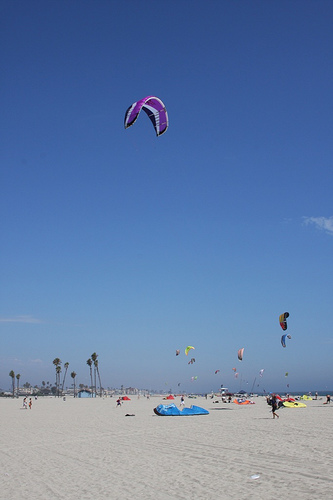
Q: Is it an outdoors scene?
A: Yes, it is outdoors.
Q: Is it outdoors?
A: Yes, it is outdoors.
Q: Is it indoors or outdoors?
A: It is outdoors.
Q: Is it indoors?
A: No, it is outdoors.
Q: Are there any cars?
A: No, there are no cars.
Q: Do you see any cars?
A: No, there are no cars.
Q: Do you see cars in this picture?
A: No, there are no cars.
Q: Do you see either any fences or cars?
A: No, there are no cars or fences.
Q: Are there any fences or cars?
A: No, there are no cars or fences.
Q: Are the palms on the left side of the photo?
A: Yes, the palms are on the left of the image.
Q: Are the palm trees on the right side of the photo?
A: No, the palm trees are on the left of the image.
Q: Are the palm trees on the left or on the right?
A: The palm trees are on the left of the image.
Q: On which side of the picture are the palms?
A: The palms are on the left of the image.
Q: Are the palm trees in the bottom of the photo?
A: Yes, the palm trees are in the bottom of the image.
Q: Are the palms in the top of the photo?
A: No, the palms are in the bottom of the image.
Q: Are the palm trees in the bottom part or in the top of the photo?
A: The palm trees are in the bottom of the image.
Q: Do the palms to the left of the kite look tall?
A: Yes, the palms are tall.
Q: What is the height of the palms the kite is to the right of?
A: The palm trees are tall.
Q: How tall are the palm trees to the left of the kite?
A: The palms are tall.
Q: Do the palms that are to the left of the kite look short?
A: No, the palms are tall.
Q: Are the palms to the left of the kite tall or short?
A: The palm trees are tall.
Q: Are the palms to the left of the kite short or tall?
A: The palm trees are tall.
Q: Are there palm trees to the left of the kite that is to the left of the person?
A: Yes, there are palm trees to the left of the kite.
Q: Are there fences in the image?
A: No, there are no fences.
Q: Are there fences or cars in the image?
A: No, there are no fences or cars.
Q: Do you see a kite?
A: Yes, there is a kite.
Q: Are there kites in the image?
A: Yes, there is a kite.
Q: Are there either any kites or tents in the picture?
A: Yes, there is a kite.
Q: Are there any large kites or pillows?
A: Yes, there is a large kite.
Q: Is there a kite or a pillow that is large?
A: Yes, the kite is large.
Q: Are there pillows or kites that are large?
A: Yes, the kite is large.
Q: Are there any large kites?
A: Yes, there is a large kite.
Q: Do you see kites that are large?
A: Yes, there is a kite that is large.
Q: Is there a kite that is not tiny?
A: Yes, there is a large kite.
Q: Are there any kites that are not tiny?
A: Yes, there is a large kite.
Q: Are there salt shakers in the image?
A: No, there are no salt shakers.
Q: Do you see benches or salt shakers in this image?
A: No, there are no salt shakers or benches.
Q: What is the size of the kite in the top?
A: The kite is large.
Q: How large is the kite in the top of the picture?
A: The kite is large.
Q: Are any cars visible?
A: No, there are no cars.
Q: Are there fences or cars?
A: No, there are no cars or fences.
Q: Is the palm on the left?
A: Yes, the palm is on the left of the image.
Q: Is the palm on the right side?
A: No, the palm is on the left of the image.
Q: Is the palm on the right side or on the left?
A: The palm is on the left of the image.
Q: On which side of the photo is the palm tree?
A: The palm tree is on the left of the image.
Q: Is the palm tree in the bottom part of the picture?
A: Yes, the palm tree is in the bottom of the image.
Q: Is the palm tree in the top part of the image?
A: No, the palm tree is in the bottom of the image.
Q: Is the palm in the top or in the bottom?
A: The palm is in the bottom of the image.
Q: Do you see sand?
A: Yes, there is sand.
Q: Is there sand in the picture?
A: Yes, there is sand.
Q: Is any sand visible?
A: Yes, there is sand.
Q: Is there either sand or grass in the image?
A: Yes, there is sand.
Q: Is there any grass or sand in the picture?
A: Yes, there is sand.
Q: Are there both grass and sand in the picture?
A: No, there is sand but no grass.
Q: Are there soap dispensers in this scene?
A: No, there are no soap dispensers.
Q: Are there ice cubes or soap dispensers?
A: No, there are no soap dispensers or ice cubes.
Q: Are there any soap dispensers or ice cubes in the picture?
A: No, there are no soap dispensers or ice cubes.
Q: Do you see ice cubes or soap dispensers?
A: No, there are no soap dispensers or ice cubes.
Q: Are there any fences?
A: No, there are no fences.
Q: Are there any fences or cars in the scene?
A: No, there are no fences or cars.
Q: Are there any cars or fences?
A: No, there are no fences or cars.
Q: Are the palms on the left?
A: Yes, the palms are on the left of the image.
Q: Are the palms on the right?
A: No, the palms are on the left of the image.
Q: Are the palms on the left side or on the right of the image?
A: The palms are on the left of the image.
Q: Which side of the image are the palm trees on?
A: The palm trees are on the left of the image.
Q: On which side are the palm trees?
A: The palm trees are on the left of the image.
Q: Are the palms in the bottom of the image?
A: Yes, the palms are in the bottom of the image.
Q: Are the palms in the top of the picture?
A: No, the palms are in the bottom of the image.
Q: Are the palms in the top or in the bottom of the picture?
A: The palms are in the bottom of the image.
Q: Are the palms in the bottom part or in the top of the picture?
A: The palms are in the bottom of the image.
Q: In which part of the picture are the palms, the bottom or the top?
A: The palms are in the bottom of the image.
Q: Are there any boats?
A: No, there are no boats.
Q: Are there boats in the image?
A: No, there are no boats.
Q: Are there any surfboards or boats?
A: No, there are no boats or surfboards.